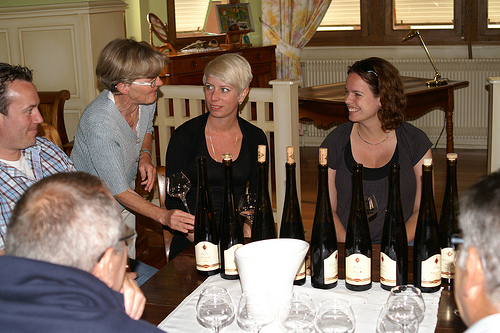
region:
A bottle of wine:
[247, 139, 282, 262]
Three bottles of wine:
[309, 144, 413, 301]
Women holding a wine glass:
[152, 164, 210, 244]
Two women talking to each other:
[88, 32, 269, 145]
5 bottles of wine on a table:
[186, 139, 341, 294]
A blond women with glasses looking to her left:
[76, 27, 182, 146]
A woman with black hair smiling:
[320, 50, 425, 153]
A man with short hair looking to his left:
[0, 48, 62, 182]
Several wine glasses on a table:
[189, 280, 369, 332]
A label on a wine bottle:
[339, 250, 374, 293]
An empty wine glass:
[195, 285, 236, 332]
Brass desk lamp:
[402, 25, 454, 86]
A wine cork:
[314, 144, 331, 165]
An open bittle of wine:
[343, 159, 373, 289]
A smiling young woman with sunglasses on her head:
[340, 58, 408, 125]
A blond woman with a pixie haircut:
[200, 49, 252, 123]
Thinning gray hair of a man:
[9, 170, 106, 257]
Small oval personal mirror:
[144, 10, 175, 56]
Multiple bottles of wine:
[192, 143, 463, 293]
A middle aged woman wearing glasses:
[96, 36, 164, 113]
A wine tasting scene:
[0, 2, 497, 332]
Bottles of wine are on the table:
[189, 142, 461, 292]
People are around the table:
[0, 37, 498, 329]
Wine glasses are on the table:
[189, 282, 431, 331]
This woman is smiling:
[341, 55, 406, 134]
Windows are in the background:
[289, 0, 499, 47]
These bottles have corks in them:
[253, 142, 332, 171]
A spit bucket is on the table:
[234, 235, 311, 327]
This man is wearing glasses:
[6, 168, 141, 290]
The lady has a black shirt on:
[166, 52, 273, 240]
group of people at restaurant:
[2, 33, 499, 330]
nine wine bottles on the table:
[183, 143, 466, 298]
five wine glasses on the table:
[177, 281, 428, 331]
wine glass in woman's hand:
[152, 160, 201, 237]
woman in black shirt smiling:
[315, 53, 443, 268]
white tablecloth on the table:
[154, 245, 448, 332]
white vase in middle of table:
[224, 232, 321, 325]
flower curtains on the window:
[253, 0, 331, 128]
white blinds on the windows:
[163, 0, 498, 26]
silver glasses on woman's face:
[121, 73, 165, 88]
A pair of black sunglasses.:
[346, 57, 378, 81]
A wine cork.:
[316, 147, 331, 164]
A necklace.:
[356, 125, 391, 148]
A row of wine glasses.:
[185, 286, 422, 330]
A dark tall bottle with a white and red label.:
[347, 160, 371, 290]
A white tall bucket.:
[234, 237, 308, 313]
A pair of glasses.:
[123, 72, 161, 91]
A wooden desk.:
[292, 58, 460, 178]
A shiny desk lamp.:
[404, 29, 446, 88]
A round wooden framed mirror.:
[147, 12, 174, 52]